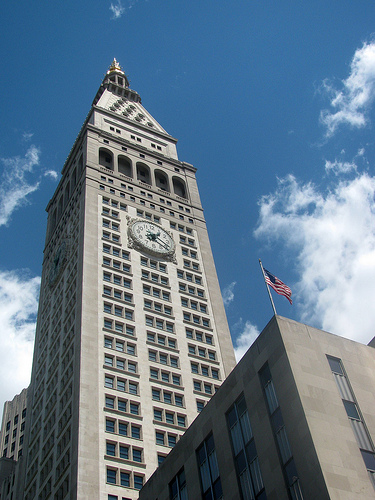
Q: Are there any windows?
A: Yes, there is a window.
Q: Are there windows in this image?
A: Yes, there is a window.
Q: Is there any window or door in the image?
A: Yes, there is a window.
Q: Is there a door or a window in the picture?
A: Yes, there is a window.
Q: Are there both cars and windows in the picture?
A: No, there is a window but no cars.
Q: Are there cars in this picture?
A: No, there are no cars.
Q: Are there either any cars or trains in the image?
A: No, there are no cars or trains.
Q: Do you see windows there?
A: Yes, there is a window.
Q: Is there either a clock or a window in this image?
A: Yes, there is a window.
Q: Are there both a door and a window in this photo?
A: No, there is a window but no doors.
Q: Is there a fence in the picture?
A: No, there are no fences.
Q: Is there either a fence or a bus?
A: No, there are no fences or buses.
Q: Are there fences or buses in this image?
A: No, there are no fences or buses.